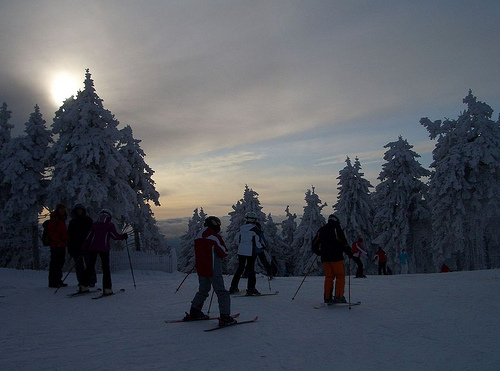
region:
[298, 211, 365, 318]
person skiing in red pants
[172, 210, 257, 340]
person standing on two skis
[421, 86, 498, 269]
snow covered pine tree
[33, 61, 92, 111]
sun behind a cloud cover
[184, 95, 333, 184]
blue sky and clouds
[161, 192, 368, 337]
three people on skis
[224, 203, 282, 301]
person in white coat on skis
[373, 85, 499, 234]
pine trees against sky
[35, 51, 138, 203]
sun behind pine tree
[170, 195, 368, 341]
group of people in snow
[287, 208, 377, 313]
person in skis in the snow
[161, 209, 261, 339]
person in skis in the snow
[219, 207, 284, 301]
person in skis in the snow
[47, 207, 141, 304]
person in skis in the snow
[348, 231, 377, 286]
person in skis in the snow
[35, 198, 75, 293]
person standing in the snow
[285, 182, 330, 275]
tree covered in snow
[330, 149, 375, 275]
tree covered in snow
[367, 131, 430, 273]
tree covered in snow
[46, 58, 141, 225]
tree covered in snow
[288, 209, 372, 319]
person wearing a pair of skis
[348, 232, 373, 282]
person wearing a pair of skis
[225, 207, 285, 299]
person wearing a pair of skis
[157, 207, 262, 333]
person wearing a pair of skis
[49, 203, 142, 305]
person wearing a pair of skis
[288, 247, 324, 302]
long metal ski pole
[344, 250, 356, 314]
long metal ski pole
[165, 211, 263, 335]
a skier with a red and white jacket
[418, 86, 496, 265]
a snow covered pine tree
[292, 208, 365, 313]
a skier with orange pants and poles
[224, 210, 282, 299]
a skier with white jacket and black pants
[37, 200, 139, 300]
two people watching a skier near them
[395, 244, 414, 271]
a skier with a blue jacket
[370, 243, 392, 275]
a skier with red jacket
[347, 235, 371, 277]
a snowboarder going down the slope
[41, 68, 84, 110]
the setting sun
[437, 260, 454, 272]
the torso of a skier going down the slope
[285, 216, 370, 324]
this is a person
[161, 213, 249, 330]
this is a person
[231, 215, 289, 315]
this is a person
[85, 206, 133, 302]
this is a person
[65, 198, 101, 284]
this is a person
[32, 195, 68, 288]
this is a person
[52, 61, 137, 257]
the tree is covered in snow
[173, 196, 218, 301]
the tree is covered in snow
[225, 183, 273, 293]
the tree is covered in snow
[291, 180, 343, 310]
the tree is covered in snow